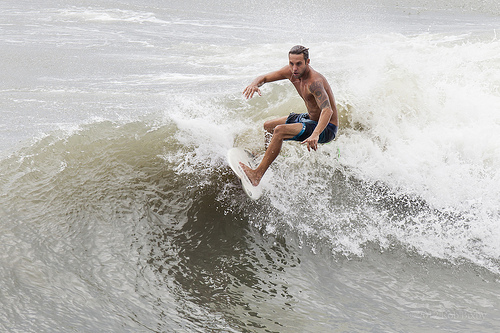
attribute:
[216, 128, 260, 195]
surfboard — white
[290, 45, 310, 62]
hair — dark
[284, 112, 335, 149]
swimsuit — blue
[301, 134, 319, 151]
hand — pointing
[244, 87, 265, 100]
hand — open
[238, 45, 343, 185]
man — white, balancing, young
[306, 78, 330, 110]
tattoo — large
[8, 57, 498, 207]
wave — rolling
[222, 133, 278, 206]
surf board — white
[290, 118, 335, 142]
trouser — black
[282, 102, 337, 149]
blue shorts — dark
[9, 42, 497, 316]
wave — big, gray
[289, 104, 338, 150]
shorts — cold, wet, board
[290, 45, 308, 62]
hair — brown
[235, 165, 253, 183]
letters — black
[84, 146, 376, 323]
water — grey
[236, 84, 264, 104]
hand — open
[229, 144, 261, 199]
surf board — nice, white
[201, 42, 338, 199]
man — tattoed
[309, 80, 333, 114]
tattoo — large, black, arm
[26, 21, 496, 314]
water — blue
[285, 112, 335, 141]
shorts — black, blue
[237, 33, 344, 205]
man — white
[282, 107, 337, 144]
trunks — blue, swim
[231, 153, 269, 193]
foot — man's, bare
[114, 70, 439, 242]
wave — natural, ocean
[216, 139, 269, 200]
surfboard — white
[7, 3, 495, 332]
water — grey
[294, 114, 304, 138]
trim — blue, light